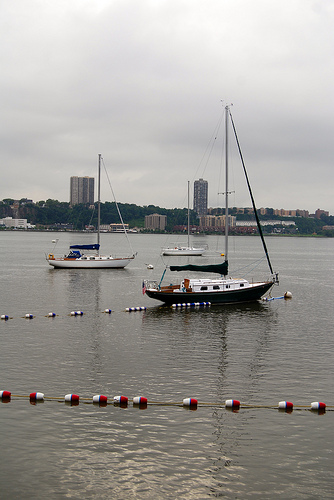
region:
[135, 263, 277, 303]
boat in bay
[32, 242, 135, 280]
white boat in bay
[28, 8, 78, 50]
white clouds in blue sky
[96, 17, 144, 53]
white clouds in blue sky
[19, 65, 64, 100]
white clouds in blue sky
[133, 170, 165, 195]
white clouds in blue sky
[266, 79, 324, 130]
white clouds in blue sky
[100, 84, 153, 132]
white clouds in blue sky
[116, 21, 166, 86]
white clouds in blue sky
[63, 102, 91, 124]
white clouds in blue sky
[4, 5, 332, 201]
the sky is overcast.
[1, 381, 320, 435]
they are floating.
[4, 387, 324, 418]
They are red and white.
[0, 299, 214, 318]
They are white and blue.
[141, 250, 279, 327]
The boat is white.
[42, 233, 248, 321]
the boats are in the water.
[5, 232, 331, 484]
The water is calm.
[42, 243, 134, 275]
The boat is white.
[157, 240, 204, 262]
the boat is white.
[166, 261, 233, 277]
the sail is black.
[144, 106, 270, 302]
a sailboat floating in the water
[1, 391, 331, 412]
a string of buoys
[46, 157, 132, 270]
a sailboat in the ocean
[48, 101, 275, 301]
three sailboats with their sails down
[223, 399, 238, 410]
a red and white buoy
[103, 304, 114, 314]
a blue and white buoy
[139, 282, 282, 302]
the hull of a sailboat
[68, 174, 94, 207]
a tall building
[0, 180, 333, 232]
the skyline of the city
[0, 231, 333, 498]
a big body of water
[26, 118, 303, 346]
Three sailboats in anchored in the water.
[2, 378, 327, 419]
Red and white floaters with blue stripe.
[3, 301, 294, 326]
Blue and white floaters.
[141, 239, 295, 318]
Sailboat with black sail.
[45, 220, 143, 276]
Sailboat with blue sail.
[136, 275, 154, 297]
American flag on stern of sailboat.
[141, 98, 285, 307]
A black and white sailboat.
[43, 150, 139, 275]
A white sailboat with blue sail.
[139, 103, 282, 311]
Mast on a black and white sailboat.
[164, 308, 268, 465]
Reflection of a boat in water.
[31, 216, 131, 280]
white boat in water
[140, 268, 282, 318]
boat in the water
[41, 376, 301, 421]
red and white net buoy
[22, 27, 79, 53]
white clouds in blue sky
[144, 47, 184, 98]
white clouds in blue sky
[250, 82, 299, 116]
white clouds in blue sky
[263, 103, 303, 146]
white clouds in blue sky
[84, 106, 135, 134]
white clouds in blue sky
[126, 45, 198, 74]
white clouds in blue sky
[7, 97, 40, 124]
white clouds in blue sky